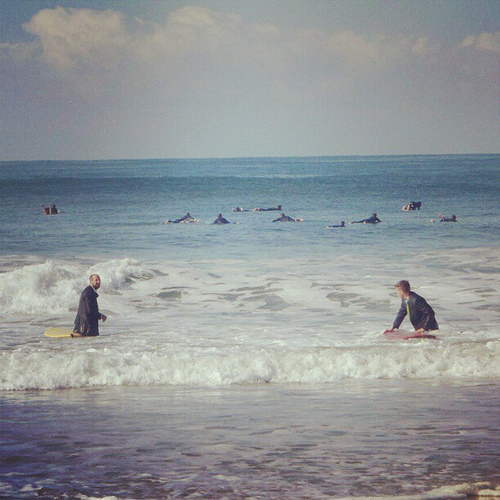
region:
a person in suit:
[375, 276, 442, 344]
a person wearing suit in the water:
[375, 277, 442, 344]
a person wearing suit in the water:
[39, 270, 116, 345]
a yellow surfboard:
[40, 323, 80, 340]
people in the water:
[34, 185, 464, 242]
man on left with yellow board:
[45, 263, 112, 353]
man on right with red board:
[379, 268, 458, 377]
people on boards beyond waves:
[43, 185, 473, 252]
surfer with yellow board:
[46, 265, 136, 387]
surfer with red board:
[379, 263, 428, 352]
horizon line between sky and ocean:
[18, 140, 483, 166]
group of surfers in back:
[181, 167, 373, 265]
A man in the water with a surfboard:
[384, 281, 440, 346]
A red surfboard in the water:
[382, 327, 434, 339]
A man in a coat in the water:
[75, 273, 102, 335]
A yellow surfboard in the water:
[42, 324, 78, 339]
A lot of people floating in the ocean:
[167, 199, 459, 226]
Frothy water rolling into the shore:
[4, 345, 499, 383]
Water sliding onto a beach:
[114, 405, 360, 462]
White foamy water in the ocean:
[149, 280, 353, 315]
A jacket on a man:
[387, 295, 435, 328]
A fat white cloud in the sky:
[19, 6, 161, 73]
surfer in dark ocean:
[382, 280, 440, 342]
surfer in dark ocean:
[43, 270, 110, 337]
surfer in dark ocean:
[168, 205, 198, 225]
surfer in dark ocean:
[213, 210, 227, 225]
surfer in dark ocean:
[232, 202, 254, 213]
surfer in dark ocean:
[259, 200, 283, 212]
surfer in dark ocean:
[275, 208, 302, 220]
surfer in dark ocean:
[333, 216, 350, 233]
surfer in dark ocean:
[349, 208, 383, 225]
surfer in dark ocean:
[403, 198, 428, 210]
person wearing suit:
[40, 269, 110, 344]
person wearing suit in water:
[41, 270, 111, 345]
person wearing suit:
[368, 276, 444, 347]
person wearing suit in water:
[368, 275, 444, 348]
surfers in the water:
[10, 192, 478, 247]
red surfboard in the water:
[378, 325, 442, 348]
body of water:
[5, 158, 493, 198]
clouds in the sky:
[2, 2, 497, 137]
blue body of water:
[8, 160, 493, 195]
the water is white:
[218, 348, 280, 379]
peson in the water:
[386, 278, 438, 332]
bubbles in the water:
[235, 279, 291, 308]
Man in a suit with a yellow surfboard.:
[40, 273, 104, 340]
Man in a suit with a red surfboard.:
[378, 279, 440, 342]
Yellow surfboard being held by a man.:
[44, 322, 79, 343]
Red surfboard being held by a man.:
[386, 325, 435, 347]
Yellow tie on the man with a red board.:
[400, 295, 417, 322]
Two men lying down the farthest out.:
[228, 201, 284, 214]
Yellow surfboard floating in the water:
[30, 320, 75, 340]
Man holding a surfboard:
[380, 276, 438, 339]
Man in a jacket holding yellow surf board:
[41, 273, 108, 345]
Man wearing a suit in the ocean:
[372, 270, 439, 345]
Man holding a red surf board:
[372, 275, 447, 347]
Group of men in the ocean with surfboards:
[37, 198, 467, 236]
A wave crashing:
[0, 343, 495, 397]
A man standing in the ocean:
[35, 268, 110, 347]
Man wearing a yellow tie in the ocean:
[377, 276, 440, 344]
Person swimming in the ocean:
[158, 211, 201, 230]